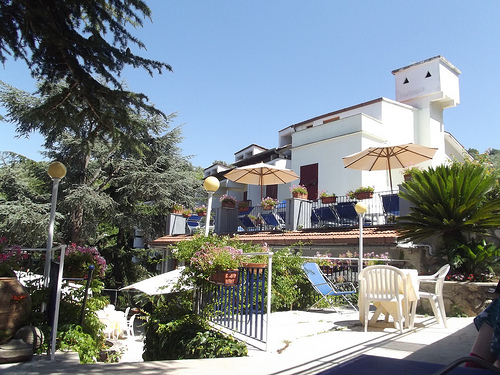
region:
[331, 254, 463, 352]
white chairs on patio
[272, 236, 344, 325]
blue chair behind white chair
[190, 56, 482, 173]
tall white building in background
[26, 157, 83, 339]
white post with lamp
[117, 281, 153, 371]
path in garden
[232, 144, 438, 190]
umbrellas used for shade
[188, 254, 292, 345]
dark bars of a fence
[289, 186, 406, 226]
blue chairs behind fence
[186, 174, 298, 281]
green plants by patio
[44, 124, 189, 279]
tall tree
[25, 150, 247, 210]
Two lights on poles.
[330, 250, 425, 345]
A white plastic chair.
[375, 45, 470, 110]
The tallest part of the building.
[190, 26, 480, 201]
The building is white.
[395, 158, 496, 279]
A small palm tree.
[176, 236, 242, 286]
Some plants growing in a planter box.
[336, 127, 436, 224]
A white umbrella.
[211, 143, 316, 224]
An umbrella next to the building.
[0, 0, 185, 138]
A green tree.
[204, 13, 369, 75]
The sky is blue.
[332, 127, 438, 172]
A white umbrella.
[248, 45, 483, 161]
The house is white.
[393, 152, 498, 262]
A little palm tree.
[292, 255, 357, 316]
A blue lounging chair.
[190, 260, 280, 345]
A little black fence.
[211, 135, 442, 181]
The two umbrellas are white.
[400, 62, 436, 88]
Triangle shapes on the building.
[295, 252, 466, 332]
Some outside lawn furniture.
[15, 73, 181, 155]
A green tree in the distance.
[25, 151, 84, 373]
round globes on outside lights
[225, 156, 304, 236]
beige umbrella poolside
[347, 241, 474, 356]
white chairs at outside table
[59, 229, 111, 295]
green shrubbery with pink flowers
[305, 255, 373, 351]
blue chair with metal frame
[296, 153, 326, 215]
burgundy door on back of house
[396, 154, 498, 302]
large green shrub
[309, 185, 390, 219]
flowers planted in boxes attached to railing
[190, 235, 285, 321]
flowers planted in boxes attached to railing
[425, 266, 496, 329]
decorative stone wall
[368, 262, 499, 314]
White patio chairs near table.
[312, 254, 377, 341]
Blue folding chair near table.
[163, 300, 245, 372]
Green plants near fence.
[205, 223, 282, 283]
Metal fence on concrete.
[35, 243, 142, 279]
Purple flowers on left.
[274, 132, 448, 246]
Large white building.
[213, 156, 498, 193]
Tan umbrellas near building.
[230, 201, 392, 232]
Blue lay out chairs near building.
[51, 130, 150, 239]
Green tree on left side.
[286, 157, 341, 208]
Brown door on white building.